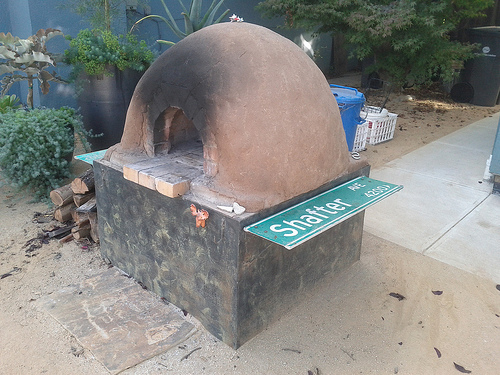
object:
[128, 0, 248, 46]
plant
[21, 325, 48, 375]
gravel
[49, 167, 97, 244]
fire wood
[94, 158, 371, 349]
stand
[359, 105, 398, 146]
plastic bin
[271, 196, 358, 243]
white letters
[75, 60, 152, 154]
container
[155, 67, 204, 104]
residue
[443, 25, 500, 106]
garbage can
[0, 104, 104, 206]
plant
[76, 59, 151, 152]
pot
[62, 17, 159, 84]
plant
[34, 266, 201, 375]
stone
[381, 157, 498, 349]
ground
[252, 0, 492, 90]
tree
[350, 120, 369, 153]
crate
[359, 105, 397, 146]
crate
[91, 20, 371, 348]
oven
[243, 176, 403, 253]
sign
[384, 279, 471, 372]
leaves